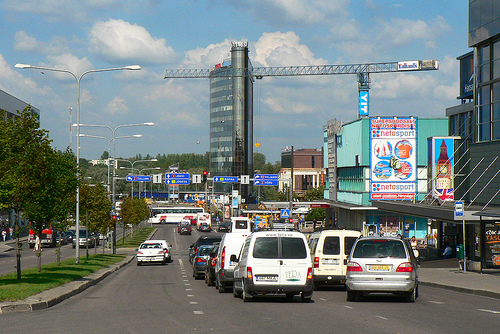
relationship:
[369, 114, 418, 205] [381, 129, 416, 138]
ad reads netosport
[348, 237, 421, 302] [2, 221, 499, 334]
van on street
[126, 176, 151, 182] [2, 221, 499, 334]
sign near street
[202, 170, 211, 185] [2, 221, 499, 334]
traffic light above street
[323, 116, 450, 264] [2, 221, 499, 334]
building near street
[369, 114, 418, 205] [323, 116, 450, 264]
ad on building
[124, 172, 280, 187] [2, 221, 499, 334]
signs above street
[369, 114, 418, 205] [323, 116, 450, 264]
ad on side of building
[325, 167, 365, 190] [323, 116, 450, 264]
windows on building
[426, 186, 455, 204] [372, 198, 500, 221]
flag above awning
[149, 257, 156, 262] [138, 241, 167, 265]
license plate on car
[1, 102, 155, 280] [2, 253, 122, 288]
trees with shadows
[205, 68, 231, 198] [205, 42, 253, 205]
side of building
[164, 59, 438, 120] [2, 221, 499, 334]
crane above street